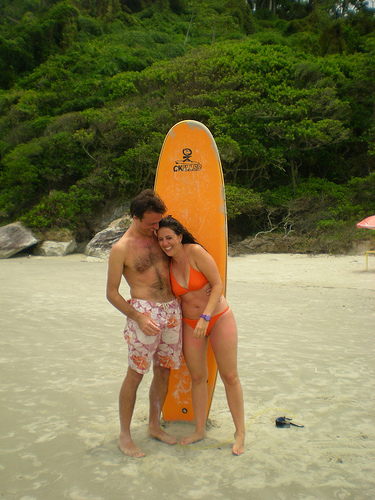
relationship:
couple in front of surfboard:
[100, 191, 264, 472] [153, 118, 227, 423]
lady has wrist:
[156, 214, 246, 456] [199, 310, 212, 322]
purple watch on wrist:
[200, 314, 211, 322] [199, 310, 212, 322]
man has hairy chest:
[105, 188, 213, 458] [129, 239, 169, 277]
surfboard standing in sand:
[153, 119, 229, 422] [0, 252, 374, 498]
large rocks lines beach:
[0, 213, 134, 260] [1, 250, 373, 498]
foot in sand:
[231, 428, 245, 458] [0, 252, 374, 498]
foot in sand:
[180, 430, 207, 446] [0, 252, 374, 498]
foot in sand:
[145, 425, 177, 446] [0, 252, 374, 498]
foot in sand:
[114, 432, 145, 459] [0, 252, 374, 498]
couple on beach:
[100, 191, 264, 472] [1, 250, 373, 498]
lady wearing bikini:
[156, 214, 246, 456] [164, 242, 230, 337]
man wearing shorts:
[114, 191, 189, 459] [124, 297, 181, 371]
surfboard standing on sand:
[153, 119, 229, 422] [0, 252, 374, 498]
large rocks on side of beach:
[0, 213, 134, 260] [1, 250, 373, 498]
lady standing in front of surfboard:
[156, 214, 246, 456] [153, 118, 227, 423]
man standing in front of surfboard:
[105, 188, 213, 458] [153, 118, 227, 423]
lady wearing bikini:
[156, 214, 246, 456] [170, 244, 230, 337]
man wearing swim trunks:
[114, 191, 189, 459] [124, 297, 181, 374]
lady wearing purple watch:
[156, 214, 246, 456] [198, 311, 218, 327]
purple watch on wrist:
[198, 311, 218, 327] [199, 310, 212, 322]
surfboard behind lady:
[153, 119, 229, 422] [156, 214, 246, 456]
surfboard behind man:
[153, 119, 229, 422] [105, 188, 213, 458]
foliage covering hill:
[1, 0, 373, 257] [3, 3, 369, 251]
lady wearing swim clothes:
[156, 214, 246, 456] [169, 244, 229, 334]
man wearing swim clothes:
[105, 188, 213, 458] [123, 297, 181, 374]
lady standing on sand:
[156, 214, 246, 456] [0, 252, 374, 498]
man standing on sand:
[105, 188, 213, 458] [0, 252, 374, 498]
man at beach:
[105, 188, 213, 458] [1, 250, 373, 498]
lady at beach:
[156, 214, 246, 456] [1, 250, 373, 498]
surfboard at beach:
[153, 118, 227, 423] [1, 250, 373, 498]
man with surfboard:
[105, 188, 213, 458] [153, 118, 227, 423]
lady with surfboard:
[156, 214, 246, 456] [153, 118, 227, 423]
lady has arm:
[155, 214, 245, 453] [193, 242, 221, 338]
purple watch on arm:
[198, 311, 218, 327] [193, 242, 221, 338]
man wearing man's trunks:
[105, 188, 213, 458] [126, 298, 192, 380]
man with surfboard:
[105, 188, 213, 458] [127, 109, 240, 420]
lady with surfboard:
[156, 214, 246, 456] [127, 109, 240, 420]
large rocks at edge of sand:
[3, 207, 152, 278] [0, 252, 374, 498]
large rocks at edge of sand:
[0, 213, 134, 260] [0, 252, 374, 498]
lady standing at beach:
[156, 214, 246, 456] [1, 250, 373, 498]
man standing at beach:
[105, 188, 213, 458] [1, 250, 373, 498]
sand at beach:
[0, 252, 374, 498] [1, 250, 373, 498]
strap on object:
[275, 413, 305, 427] [268, 413, 311, 438]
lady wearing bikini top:
[156, 214, 246, 456] [169, 243, 207, 296]